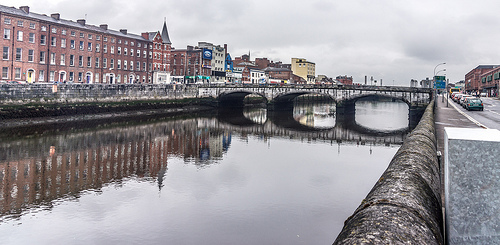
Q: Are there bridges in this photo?
A: Yes, there is a bridge.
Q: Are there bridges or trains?
A: Yes, there is a bridge.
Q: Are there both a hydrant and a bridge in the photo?
A: No, there is a bridge but no fire hydrants.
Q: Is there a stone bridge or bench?
A: Yes, there is a stone bridge.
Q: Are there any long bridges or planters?
A: Yes, there is a long bridge.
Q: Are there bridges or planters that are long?
A: Yes, the bridge is long.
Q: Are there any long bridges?
A: Yes, there is a long bridge.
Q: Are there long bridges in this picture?
A: Yes, there is a long bridge.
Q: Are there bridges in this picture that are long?
A: Yes, there is a bridge that is long.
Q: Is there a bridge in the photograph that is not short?
A: Yes, there is a long bridge.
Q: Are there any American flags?
A: No, there are no American flags.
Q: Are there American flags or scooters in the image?
A: No, there are no American flags or scooters.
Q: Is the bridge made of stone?
A: Yes, the bridge is made of stone.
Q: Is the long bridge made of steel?
A: No, the bridge is made of stone.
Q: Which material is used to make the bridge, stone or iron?
A: The bridge is made of stone.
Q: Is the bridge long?
A: Yes, the bridge is long.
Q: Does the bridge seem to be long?
A: Yes, the bridge is long.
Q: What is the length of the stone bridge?
A: The bridge is long.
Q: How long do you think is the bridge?
A: The bridge is long.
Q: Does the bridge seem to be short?
A: No, the bridge is long.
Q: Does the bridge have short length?
A: No, the bridge is long.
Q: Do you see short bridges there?
A: No, there is a bridge but it is long.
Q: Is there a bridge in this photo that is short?
A: No, there is a bridge but it is long.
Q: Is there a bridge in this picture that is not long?
A: No, there is a bridge but it is long.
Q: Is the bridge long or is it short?
A: The bridge is long.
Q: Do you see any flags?
A: No, there are no flags.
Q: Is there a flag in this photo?
A: No, there are no flags.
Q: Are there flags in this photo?
A: No, there are no flags.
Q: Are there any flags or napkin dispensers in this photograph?
A: No, there are no flags or napkin dispensers.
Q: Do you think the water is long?
A: Yes, the water is long.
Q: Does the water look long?
A: Yes, the water is long.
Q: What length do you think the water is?
A: The water is long.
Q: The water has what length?
A: The water is long.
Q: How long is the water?
A: The water is long.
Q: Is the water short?
A: No, the water is long.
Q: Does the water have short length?
A: No, the water is long.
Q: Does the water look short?
A: No, the water is long.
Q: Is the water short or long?
A: The water is long.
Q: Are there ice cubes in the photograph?
A: No, there are no ice cubes.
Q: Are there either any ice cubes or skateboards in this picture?
A: No, there are no ice cubes or skateboards.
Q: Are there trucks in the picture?
A: No, there are no trucks.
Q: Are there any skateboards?
A: No, there are no skateboards.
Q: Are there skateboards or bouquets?
A: No, there are no skateboards or bouquets.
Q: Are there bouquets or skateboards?
A: No, there are no skateboards or bouquets.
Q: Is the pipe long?
A: Yes, the pipe is long.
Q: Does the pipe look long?
A: Yes, the pipe is long.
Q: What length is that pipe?
A: The pipe is long.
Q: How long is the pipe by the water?
A: The pipe is long.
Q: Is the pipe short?
A: No, the pipe is long.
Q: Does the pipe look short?
A: No, the pipe is long.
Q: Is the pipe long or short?
A: The pipe is long.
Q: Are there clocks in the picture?
A: No, there are no clocks.